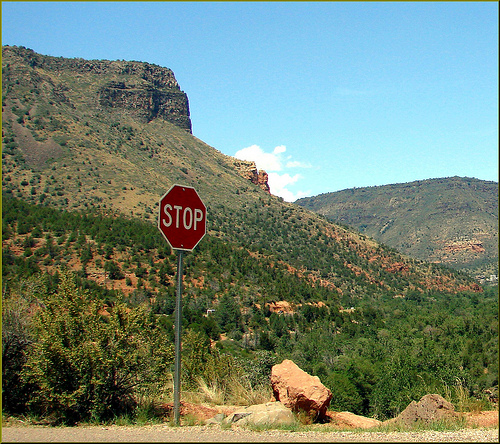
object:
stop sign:
[158, 183, 206, 427]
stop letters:
[163, 204, 204, 231]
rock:
[271, 358, 334, 425]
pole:
[173, 250, 184, 427]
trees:
[125, 276, 132, 286]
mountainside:
[0, 114, 485, 292]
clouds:
[231, 145, 286, 175]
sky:
[0, 0, 500, 203]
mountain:
[140, 118, 270, 433]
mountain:
[293, 174, 500, 286]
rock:
[394, 394, 456, 430]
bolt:
[183, 188, 186, 191]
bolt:
[181, 244, 184, 246]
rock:
[221, 401, 296, 426]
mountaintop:
[0, 44, 192, 134]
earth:
[0, 46, 487, 317]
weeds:
[194, 373, 225, 405]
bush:
[1, 263, 175, 428]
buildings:
[475, 274, 486, 284]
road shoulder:
[0, 401, 500, 443]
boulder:
[257, 168, 271, 195]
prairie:
[224, 289, 499, 422]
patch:
[264, 300, 302, 318]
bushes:
[179, 325, 257, 405]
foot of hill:
[0, 191, 500, 434]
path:
[0, 425, 500, 442]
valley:
[392, 263, 484, 299]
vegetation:
[0, 45, 483, 288]